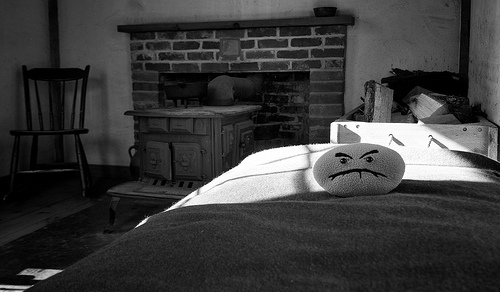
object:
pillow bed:
[28, 141, 498, 292]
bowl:
[313, 7, 338, 16]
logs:
[328, 67, 476, 145]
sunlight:
[199, 142, 483, 203]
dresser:
[105, 105, 262, 231]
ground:
[2, 200, 69, 277]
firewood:
[361, 77, 395, 122]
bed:
[25, 142, 498, 289]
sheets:
[22, 146, 497, 292]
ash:
[168, 104, 248, 114]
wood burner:
[99, 100, 258, 236]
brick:
[250, 38, 289, 49]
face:
[321, 147, 392, 187]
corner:
[2, 4, 121, 174]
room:
[0, 1, 497, 290]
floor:
[1, 173, 150, 290]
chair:
[0, 66, 95, 197]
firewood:
[415, 114, 461, 125]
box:
[330, 113, 495, 153]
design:
[322, 147, 386, 183]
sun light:
[6, 268, 62, 280]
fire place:
[100, 14, 351, 234]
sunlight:
[333, 121, 477, 144]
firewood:
[404, 93, 446, 120]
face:
[311, 138, 397, 187]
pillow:
[308, 141, 410, 195]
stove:
[97, 75, 273, 226]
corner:
[327, 2, 498, 149]